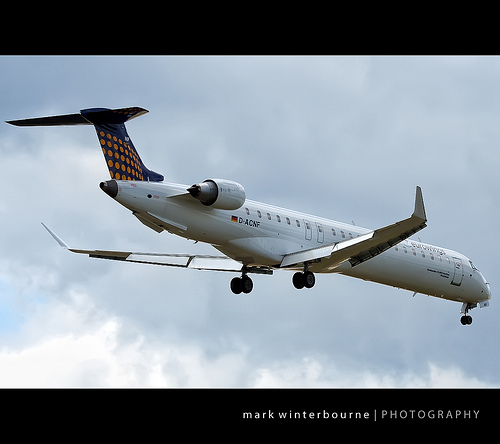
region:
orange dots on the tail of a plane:
[95, 124, 165, 210]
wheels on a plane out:
[218, 254, 338, 307]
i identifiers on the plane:
[212, 207, 289, 239]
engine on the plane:
[182, 151, 275, 246]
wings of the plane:
[258, 213, 427, 288]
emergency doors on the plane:
[294, 214, 330, 247]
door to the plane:
[441, 246, 488, 311]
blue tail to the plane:
[9, 103, 241, 243]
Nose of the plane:
[442, 240, 498, 337]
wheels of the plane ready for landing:
[224, 230, 474, 306]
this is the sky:
[204, 80, 255, 128]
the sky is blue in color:
[222, 88, 295, 143]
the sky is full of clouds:
[243, 72, 465, 144]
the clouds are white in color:
[28, 297, 130, 378]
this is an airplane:
[4, 82, 493, 330]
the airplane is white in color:
[381, 255, 404, 280]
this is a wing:
[289, 182, 430, 272]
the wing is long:
[288, 183, 427, 270]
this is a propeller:
[183, 174, 249, 213]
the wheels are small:
[234, 279, 242, 290]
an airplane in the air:
[40, 40, 486, 337]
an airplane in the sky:
[41, 59, 498, 404]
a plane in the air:
[22, 78, 499, 387]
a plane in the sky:
[16, 59, 483, 352]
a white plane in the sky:
[37, 59, 497, 355]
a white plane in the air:
[41, 70, 497, 341]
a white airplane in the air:
[29, 82, 496, 320]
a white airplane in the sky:
[19, 77, 498, 399]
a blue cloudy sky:
[204, 60, 374, 165]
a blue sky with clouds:
[235, 64, 375, 146]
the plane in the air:
[7, 97, 495, 347]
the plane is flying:
[1, 100, 496, 330]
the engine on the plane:
[175, 170, 255, 215]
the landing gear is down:
[217, 261, 482, 326]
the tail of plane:
[6, 91, 151, 172]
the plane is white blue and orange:
[0, 96, 492, 326]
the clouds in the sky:
[275, 102, 442, 154]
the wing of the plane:
[276, 182, 436, 287]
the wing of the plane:
[33, 203, 237, 283]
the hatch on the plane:
[445, 253, 465, 288]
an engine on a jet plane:
[185, 175, 250, 209]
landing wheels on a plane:
[229, 272, 254, 294]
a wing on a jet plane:
[270, 181, 426, 271]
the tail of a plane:
[5, 105, 157, 179]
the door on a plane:
[303, 216, 314, 241]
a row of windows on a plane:
[245, 205, 300, 230]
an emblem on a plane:
[229, 210, 261, 230]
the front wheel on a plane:
[458, 298, 479, 326]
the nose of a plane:
[474, 272, 497, 312]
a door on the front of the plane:
[452, 258, 466, 290]